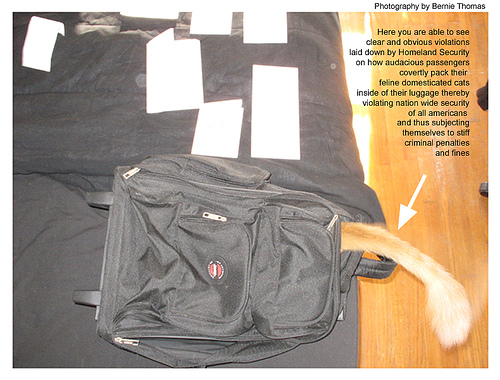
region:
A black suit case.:
[81, 145, 346, 360]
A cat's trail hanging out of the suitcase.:
[337, 185, 472, 355]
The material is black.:
[38, 90, 99, 150]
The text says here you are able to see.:
[368, 20, 473, 35]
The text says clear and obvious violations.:
[365, 35, 472, 46]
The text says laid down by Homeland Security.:
[341, 43, 469, 55]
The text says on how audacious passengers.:
[350, 55, 477, 65]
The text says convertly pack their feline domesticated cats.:
[361, 65, 474, 87]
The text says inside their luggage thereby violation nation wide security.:
[351, 83, 474, 108]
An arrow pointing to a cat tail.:
[358, 164, 483, 360]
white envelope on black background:
[219, 47, 333, 178]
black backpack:
[87, 138, 334, 360]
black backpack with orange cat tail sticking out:
[112, 170, 475, 355]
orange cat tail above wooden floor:
[370, 235, 480, 355]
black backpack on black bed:
[48, 134, 293, 373]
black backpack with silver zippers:
[85, 165, 295, 350]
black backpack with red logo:
[98, 155, 321, 375]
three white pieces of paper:
[130, 33, 320, 156]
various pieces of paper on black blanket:
[18, 20, 328, 157]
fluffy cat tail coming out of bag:
[307, 172, 469, 347]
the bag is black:
[181, 298, 198, 333]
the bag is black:
[227, 317, 244, 359]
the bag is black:
[219, 287, 234, 322]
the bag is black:
[225, 305, 232, 332]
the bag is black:
[223, 306, 238, 338]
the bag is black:
[197, 277, 216, 317]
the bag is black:
[211, 304, 228, 324]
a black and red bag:
[78, 158, 342, 364]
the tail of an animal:
[338, 223, 472, 345]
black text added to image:
[350, 23, 475, 157]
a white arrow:
[393, 173, 433, 228]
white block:
[251, 63, 301, 159]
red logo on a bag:
[205, 256, 229, 283]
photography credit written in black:
[370, 1, 487, 13]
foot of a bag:
[72, 287, 101, 307]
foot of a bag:
[85, 186, 114, 211]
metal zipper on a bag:
[124, 165, 141, 181]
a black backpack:
[84, 140, 391, 357]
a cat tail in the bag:
[279, 175, 480, 359]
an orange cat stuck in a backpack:
[88, 125, 475, 362]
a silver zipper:
[190, 188, 227, 230]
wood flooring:
[385, 124, 466, 244]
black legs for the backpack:
[65, 167, 132, 333]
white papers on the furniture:
[109, 24, 344, 177]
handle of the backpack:
[343, 220, 403, 305]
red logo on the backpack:
[186, 232, 243, 308]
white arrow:
[364, 157, 441, 253]